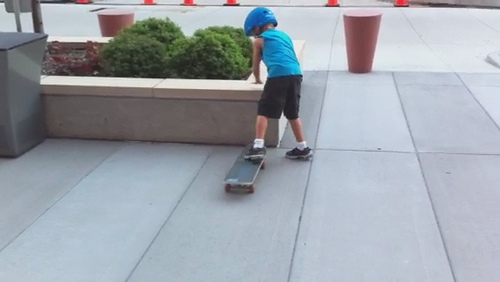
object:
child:
[241, 6, 313, 162]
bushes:
[100, 16, 252, 80]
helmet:
[244, 6, 276, 33]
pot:
[339, 9, 383, 73]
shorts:
[256, 75, 303, 120]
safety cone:
[322, 1, 339, 9]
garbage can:
[0, 30, 45, 158]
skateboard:
[220, 146, 265, 193]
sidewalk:
[0, 1, 499, 65]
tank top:
[255, 28, 303, 79]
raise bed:
[45, 40, 102, 76]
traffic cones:
[75, 1, 412, 7]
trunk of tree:
[27, 0, 54, 64]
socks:
[250, 138, 310, 152]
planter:
[39, 18, 305, 149]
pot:
[93, 8, 134, 37]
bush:
[167, 26, 250, 80]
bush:
[98, 32, 165, 79]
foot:
[243, 144, 268, 162]